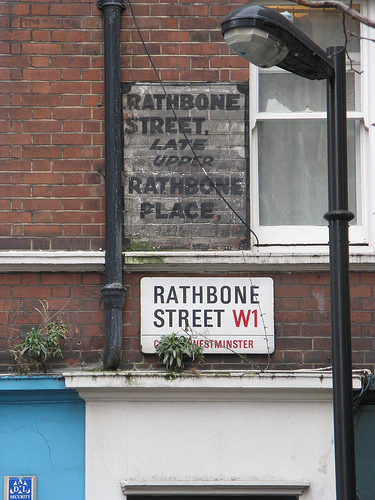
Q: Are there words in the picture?
A: Yes, there are words.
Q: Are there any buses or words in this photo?
A: Yes, there are words.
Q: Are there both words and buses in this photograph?
A: No, there are words but no buses.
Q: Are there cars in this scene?
A: No, there are no cars.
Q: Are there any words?
A: Yes, there are words.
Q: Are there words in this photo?
A: Yes, there are words.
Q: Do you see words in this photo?
A: Yes, there are words.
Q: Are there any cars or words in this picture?
A: Yes, there are words.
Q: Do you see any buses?
A: No, there are no buses.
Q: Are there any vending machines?
A: No, there are no vending machines.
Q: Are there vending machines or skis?
A: No, there are no vending machines or skis.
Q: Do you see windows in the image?
A: Yes, there is a window.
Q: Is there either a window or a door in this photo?
A: Yes, there is a window.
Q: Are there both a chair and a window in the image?
A: No, there is a window but no chairs.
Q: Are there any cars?
A: No, there are no cars.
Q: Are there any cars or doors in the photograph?
A: No, there are no cars or doors.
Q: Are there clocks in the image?
A: No, there are no clocks.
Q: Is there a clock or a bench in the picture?
A: No, there are no clocks or benches.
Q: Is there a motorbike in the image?
A: No, there are no motorcycles.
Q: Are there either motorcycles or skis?
A: No, there are no motorcycles or skis.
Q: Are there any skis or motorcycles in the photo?
A: No, there are no motorcycles or skis.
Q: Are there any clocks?
A: No, there are no clocks.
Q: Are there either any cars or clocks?
A: No, there are no clocks or cars.